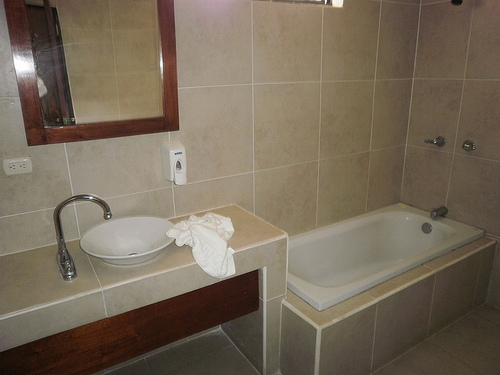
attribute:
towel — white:
[165, 211, 237, 281]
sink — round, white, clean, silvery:
[77, 215, 178, 268]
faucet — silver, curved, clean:
[51, 193, 113, 280]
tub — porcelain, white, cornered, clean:
[288, 199, 485, 311]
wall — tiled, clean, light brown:
[0, 0, 425, 257]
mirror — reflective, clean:
[22, 0, 168, 129]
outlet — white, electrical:
[1, 155, 36, 180]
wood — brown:
[1, 0, 180, 147]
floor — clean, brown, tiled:
[375, 303, 499, 373]